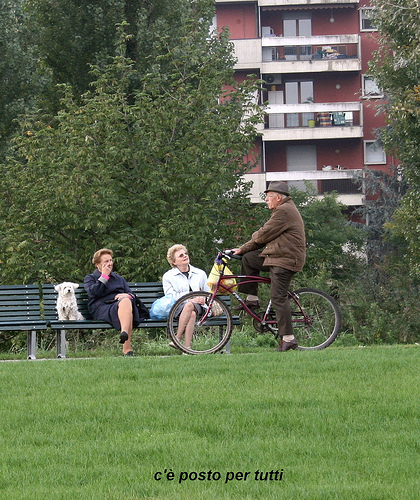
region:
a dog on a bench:
[48, 277, 78, 326]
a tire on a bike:
[297, 281, 335, 349]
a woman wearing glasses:
[176, 245, 192, 263]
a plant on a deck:
[300, 92, 321, 132]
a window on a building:
[363, 137, 390, 176]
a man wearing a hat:
[258, 176, 292, 195]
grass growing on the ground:
[71, 354, 109, 381]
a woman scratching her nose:
[89, 250, 122, 283]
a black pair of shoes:
[113, 324, 146, 370]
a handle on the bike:
[225, 245, 249, 270]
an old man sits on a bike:
[165, 177, 345, 363]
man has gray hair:
[239, 175, 313, 242]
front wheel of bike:
[162, 289, 235, 359]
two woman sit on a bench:
[78, 234, 223, 357]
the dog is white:
[48, 277, 85, 325]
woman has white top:
[150, 235, 224, 352]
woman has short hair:
[76, 239, 151, 356]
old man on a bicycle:
[166, 180, 339, 351]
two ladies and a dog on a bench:
[47, 241, 239, 356]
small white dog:
[52, 280, 85, 318]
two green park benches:
[1, 284, 238, 353]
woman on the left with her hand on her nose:
[84, 248, 146, 354]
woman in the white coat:
[160, 243, 217, 352]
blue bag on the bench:
[151, 294, 176, 318]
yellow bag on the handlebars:
[209, 253, 235, 290]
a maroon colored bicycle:
[167, 246, 339, 350]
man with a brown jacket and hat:
[239, 177, 306, 351]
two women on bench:
[37, 211, 265, 385]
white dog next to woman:
[56, 280, 76, 325]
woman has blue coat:
[80, 261, 114, 299]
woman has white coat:
[145, 278, 218, 303]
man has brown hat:
[259, 171, 293, 217]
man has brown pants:
[247, 265, 304, 332]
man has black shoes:
[273, 342, 294, 358]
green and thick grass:
[111, 362, 311, 467]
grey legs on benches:
[30, 327, 94, 364]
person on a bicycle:
[163, 172, 348, 360]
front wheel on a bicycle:
[161, 287, 239, 358]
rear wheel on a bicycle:
[275, 284, 347, 352]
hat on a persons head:
[260, 177, 293, 199]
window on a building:
[359, 136, 390, 168]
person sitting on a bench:
[79, 239, 155, 363]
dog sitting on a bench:
[47, 275, 90, 327]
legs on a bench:
[51, 322, 72, 364]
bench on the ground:
[0, 278, 49, 366]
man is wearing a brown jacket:
[273, 209, 306, 262]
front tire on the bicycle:
[171, 292, 231, 350]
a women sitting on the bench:
[83, 248, 152, 344]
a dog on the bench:
[54, 279, 88, 321]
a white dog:
[57, 282, 81, 322]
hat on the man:
[261, 180, 292, 196]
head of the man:
[265, 191, 288, 209]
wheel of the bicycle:
[282, 290, 345, 354]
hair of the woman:
[160, 246, 175, 253]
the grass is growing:
[75, 454, 130, 479]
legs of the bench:
[15, 327, 73, 357]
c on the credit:
[144, 464, 166, 485]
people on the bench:
[82, 250, 180, 349]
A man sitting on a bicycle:
[167, 181, 341, 354]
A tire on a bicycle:
[165, 290, 233, 353]